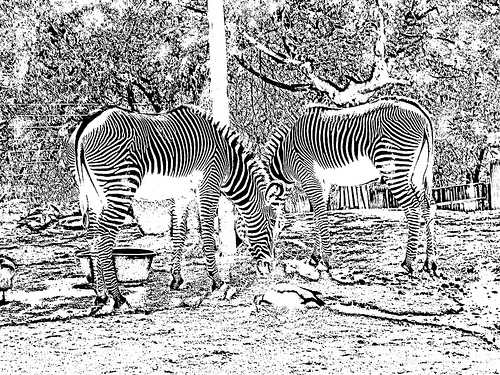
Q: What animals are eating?
A: Zebras.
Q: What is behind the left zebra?
A: A pole.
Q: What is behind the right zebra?
A: A tree.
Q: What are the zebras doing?
A: Eating.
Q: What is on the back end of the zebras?
A: Tails.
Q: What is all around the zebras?
A: Trees.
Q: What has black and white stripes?
A: Zebras.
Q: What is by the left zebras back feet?
A: A bucket.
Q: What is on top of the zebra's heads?
A: Ears.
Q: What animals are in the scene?
A: Zebras.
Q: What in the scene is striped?
A: The zebra.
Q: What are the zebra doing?
A: Eating.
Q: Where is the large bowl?
A: Near the zebra on the left.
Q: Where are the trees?
A: In the distance.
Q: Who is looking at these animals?
A: The photographer.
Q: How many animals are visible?
A: Two.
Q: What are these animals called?
A: Zebras.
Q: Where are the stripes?
A: On the zebras.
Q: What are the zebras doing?
A: Grazing.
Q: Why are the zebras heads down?
A: They're eating grass.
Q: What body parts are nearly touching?
A: The zebras heads.